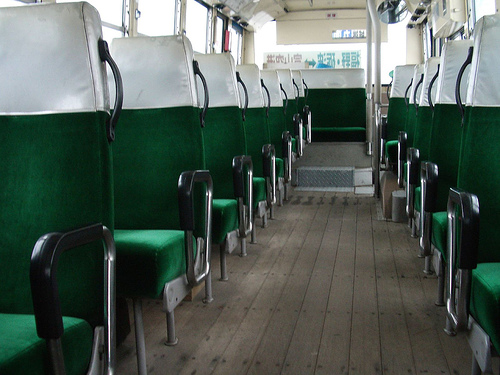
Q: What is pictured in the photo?
A: Green seats.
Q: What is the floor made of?
A: Wood.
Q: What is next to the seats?
A: Armrests.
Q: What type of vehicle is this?
A: Bus.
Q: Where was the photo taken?
A: Inside a bus.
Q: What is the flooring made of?
A: Wood.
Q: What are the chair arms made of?
A: Metal.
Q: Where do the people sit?
A: On the seats.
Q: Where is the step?
A: In the aisle.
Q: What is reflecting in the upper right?
A: A mirror.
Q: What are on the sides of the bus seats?
A: Handles.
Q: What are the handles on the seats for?
A: Stability.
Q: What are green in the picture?
A: Seat cushions.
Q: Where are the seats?
A: On a bus.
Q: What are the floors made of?
A: Wood.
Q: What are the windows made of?
A: Glass.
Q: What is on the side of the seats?
A: Arm rests.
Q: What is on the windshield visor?
A: A mirror.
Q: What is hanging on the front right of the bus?
A: A mirror.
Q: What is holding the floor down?
A: Screws.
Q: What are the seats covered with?
A: Nylon.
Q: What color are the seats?
A: Green and white.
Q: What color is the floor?
A: Gray.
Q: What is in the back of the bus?
A: One big seat.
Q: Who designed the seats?
A: The bus owner.